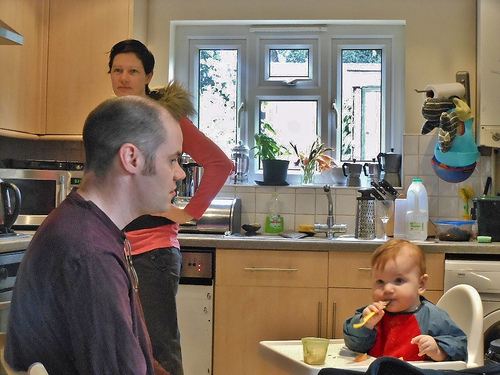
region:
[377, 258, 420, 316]
Baby with spoon in mouth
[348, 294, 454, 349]
Baby wearing red shirt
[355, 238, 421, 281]
Baby with red hair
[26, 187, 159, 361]
Man wearing purple shirt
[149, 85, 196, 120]
Man with green hair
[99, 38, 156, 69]
Woman with black hair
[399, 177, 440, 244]
Container on top on counter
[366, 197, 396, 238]
Glass on counter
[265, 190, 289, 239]
Dish washing liquid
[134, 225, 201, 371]
Woman wearing black pants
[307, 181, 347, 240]
a chrome kitchen faucet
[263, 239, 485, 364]
a baby sitting in high chair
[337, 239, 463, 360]
baby with spoon in mouth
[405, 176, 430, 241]
a clear water bottle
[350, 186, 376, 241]
a metal cheese grater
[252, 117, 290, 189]
a green potted plant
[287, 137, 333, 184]
a clear vase with flowers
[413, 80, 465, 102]
a paper towel holder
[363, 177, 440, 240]
a knife block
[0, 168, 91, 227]
a brush aluminum microwave oven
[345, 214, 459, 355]
a baby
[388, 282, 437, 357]
a baby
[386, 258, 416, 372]
a baby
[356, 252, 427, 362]
a baby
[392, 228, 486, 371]
a baby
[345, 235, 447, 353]
this is a child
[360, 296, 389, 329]
he is holding a spoon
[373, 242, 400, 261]
the hair is short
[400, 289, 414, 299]
the cheeks are fat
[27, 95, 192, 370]
this is a man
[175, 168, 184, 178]
the nose is long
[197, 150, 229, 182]
the elbow is bent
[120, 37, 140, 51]
the hair is black in color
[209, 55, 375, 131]
the windows are closed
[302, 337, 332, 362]
this is a cup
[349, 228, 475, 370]
baby wearing red and grey tshirt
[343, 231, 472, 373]
baby holding yellow spoon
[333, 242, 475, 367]
baby eating from small yellow spoon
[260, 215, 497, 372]
baby sitting in high chair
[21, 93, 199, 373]
man with balding dark hair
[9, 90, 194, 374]
man in maroon tshirt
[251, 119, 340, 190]
plants on windowsill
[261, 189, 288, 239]
clear bottle of dish soap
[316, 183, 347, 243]
silver metal sink faucet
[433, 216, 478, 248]
plastic bowl with lid